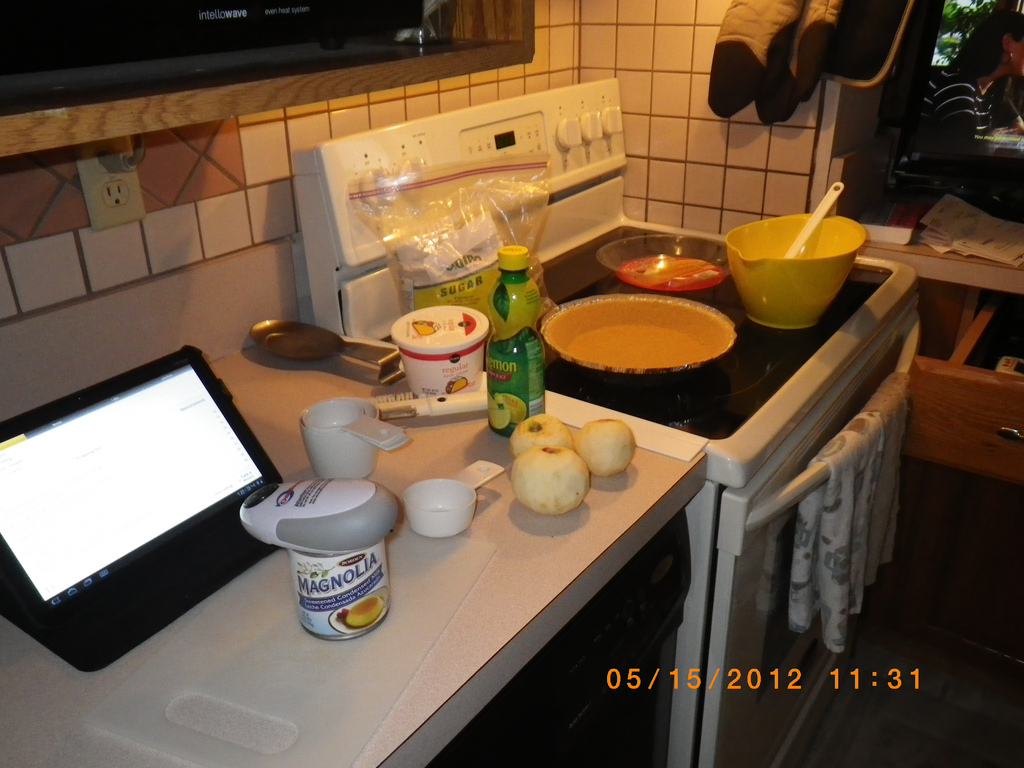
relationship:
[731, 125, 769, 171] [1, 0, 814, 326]
tile in a wall wall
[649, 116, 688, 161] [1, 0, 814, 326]
tile in a wall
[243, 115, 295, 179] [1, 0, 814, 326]
tile in a wall